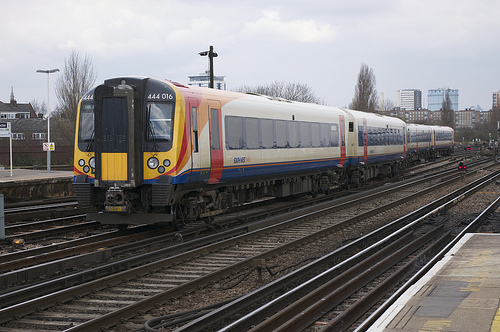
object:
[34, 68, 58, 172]
street lamp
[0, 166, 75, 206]
railway platform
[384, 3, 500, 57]
clouds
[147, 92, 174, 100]
number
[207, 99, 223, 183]
door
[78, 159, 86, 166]
lights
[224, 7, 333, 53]
cloud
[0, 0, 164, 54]
cloud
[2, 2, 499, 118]
sky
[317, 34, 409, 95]
clouds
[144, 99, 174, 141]
windshield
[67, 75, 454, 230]
train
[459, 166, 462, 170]
lights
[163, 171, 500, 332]
tracks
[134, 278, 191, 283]
sleeper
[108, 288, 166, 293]
sleeper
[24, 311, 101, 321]
sleeper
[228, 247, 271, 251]
sleeper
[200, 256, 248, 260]
sleeper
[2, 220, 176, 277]
track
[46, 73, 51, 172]
pole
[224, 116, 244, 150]
windows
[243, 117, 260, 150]
windows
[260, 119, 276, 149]
windows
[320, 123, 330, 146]
windows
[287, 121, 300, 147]
windows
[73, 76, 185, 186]
yellow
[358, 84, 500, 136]
buildings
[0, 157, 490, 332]
railway